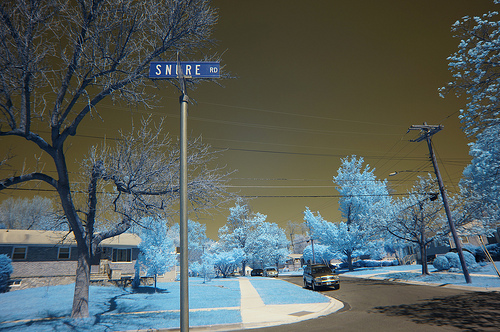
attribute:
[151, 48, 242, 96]
sign — tall, blue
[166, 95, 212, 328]
pole — tall, crooked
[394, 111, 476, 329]
utility pole — here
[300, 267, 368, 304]
suv — here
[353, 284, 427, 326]
road — here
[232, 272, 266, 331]
sidewalk — plowed, here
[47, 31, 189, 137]
foliage — bare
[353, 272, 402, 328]
street — here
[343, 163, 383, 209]
tree — tall, leaveless, blue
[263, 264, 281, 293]
car — parked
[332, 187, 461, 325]
park — beautiful